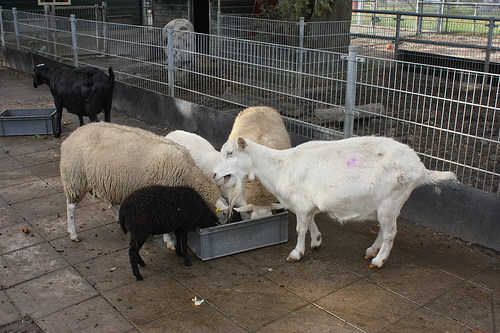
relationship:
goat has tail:
[213, 136, 459, 268] [425, 168, 459, 188]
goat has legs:
[213, 136, 459, 268] [283, 213, 399, 267]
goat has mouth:
[213, 136, 459, 268] [214, 171, 237, 189]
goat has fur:
[60, 121, 234, 241] [60, 121, 221, 217]